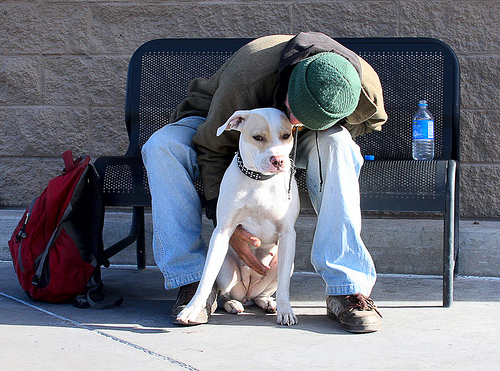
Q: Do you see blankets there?
A: No, there are no blankets.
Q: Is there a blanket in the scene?
A: No, there are no blankets.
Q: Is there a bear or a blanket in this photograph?
A: No, there are no blankets or bears.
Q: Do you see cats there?
A: No, there are no cats.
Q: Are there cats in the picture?
A: No, there are no cats.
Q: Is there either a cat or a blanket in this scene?
A: No, there are no cats or blankets.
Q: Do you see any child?
A: No, there are no children.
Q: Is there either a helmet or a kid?
A: No, there are no children or helmets.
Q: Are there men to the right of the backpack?
A: Yes, there is a man to the right of the backpack.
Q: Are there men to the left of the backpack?
A: No, the man is to the right of the backpack.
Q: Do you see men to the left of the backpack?
A: No, the man is to the right of the backpack.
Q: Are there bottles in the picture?
A: Yes, there is a bottle.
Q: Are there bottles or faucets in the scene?
A: Yes, there is a bottle.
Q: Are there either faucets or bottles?
A: Yes, there is a bottle.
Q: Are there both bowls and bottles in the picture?
A: No, there is a bottle but no bowls.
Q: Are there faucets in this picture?
A: No, there are no faucets.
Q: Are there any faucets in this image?
A: No, there are no faucets.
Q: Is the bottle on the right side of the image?
A: Yes, the bottle is on the right of the image.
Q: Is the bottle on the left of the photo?
A: No, the bottle is on the right of the image.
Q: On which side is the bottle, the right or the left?
A: The bottle is on the right of the image.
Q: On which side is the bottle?
A: The bottle is on the right of the image.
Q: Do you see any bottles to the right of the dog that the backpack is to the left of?
A: Yes, there is a bottle to the right of the dog.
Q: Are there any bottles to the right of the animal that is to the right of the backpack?
A: Yes, there is a bottle to the right of the dog.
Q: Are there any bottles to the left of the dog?
A: No, the bottle is to the right of the dog.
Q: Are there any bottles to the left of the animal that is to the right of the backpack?
A: No, the bottle is to the right of the dog.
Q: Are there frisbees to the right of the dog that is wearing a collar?
A: No, there is a bottle to the right of the dog.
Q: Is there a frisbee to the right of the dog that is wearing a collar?
A: No, there is a bottle to the right of the dog.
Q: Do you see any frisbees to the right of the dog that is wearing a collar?
A: No, there is a bottle to the right of the dog.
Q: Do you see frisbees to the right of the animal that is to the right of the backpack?
A: No, there is a bottle to the right of the dog.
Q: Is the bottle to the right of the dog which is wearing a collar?
A: Yes, the bottle is to the right of the dog.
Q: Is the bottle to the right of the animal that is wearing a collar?
A: Yes, the bottle is to the right of the dog.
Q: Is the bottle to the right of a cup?
A: No, the bottle is to the right of the dog.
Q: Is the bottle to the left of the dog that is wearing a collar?
A: No, the bottle is to the right of the dog.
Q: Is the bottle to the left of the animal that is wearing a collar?
A: No, the bottle is to the right of the dog.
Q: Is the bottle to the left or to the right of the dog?
A: The bottle is to the right of the dog.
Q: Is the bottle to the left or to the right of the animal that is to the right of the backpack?
A: The bottle is to the right of the dog.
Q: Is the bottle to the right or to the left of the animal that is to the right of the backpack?
A: The bottle is to the right of the dog.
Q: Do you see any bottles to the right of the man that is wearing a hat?
A: Yes, there is a bottle to the right of the man.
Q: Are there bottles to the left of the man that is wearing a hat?
A: No, the bottle is to the right of the man.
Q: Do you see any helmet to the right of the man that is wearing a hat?
A: No, there is a bottle to the right of the man.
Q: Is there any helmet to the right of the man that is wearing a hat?
A: No, there is a bottle to the right of the man.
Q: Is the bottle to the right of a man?
A: Yes, the bottle is to the right of a man.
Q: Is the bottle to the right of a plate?
A: No, the bottle is to the right of a man.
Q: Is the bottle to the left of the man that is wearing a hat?
A: No, the bottle is to the right of the man.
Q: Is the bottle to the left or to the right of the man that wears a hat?
A: The bottle is to the right of the man.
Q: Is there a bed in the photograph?
A: No, there are no beds.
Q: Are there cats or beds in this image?
A: No, there are no beds or cats.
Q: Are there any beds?
A: No, there are no beds.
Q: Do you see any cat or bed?
A: No, there are no beds or cats.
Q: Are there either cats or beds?
A: No, there are no beds or cats.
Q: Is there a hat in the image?
A: Yes, there is a hat.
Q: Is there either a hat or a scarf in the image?
A: Yes, there is a hat.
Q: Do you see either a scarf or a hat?
A: Yes, there is a hat.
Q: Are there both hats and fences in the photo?
A: No, there is a hat but no fences.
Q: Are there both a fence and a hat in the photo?
A: No, there is a hat but no fences.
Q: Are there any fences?
A: No, there are no fences.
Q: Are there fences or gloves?
A: No, there are no fences or gloves.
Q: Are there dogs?
A: Yes, there is a dog.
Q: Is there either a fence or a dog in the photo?
A: Yes, there is a dog.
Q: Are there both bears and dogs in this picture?
A: No, there is a dog but no bears.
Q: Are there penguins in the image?
A: No, there are no penguins.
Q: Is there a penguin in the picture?
A: No, there are no penguins.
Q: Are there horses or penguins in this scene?
A: No, there are no penguins or horses.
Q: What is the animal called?
A: The animal is a dog.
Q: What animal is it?
A: The animal is a dog.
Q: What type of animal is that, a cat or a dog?
A: That is a dog.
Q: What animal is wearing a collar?
A: The dog is wearing a collar.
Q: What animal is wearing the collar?
A: The dog is wearing a collar.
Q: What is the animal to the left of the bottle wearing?
A: The dog is wearing a collar.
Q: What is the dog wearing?
A: The dog is wearing a collar.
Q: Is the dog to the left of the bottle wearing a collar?
A: Yes, the dog is wearing a collar.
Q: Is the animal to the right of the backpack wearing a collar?
A: Yes, the dog is wearing a collar.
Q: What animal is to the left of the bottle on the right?
A: The animal is a dog.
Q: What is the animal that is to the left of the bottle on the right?
A: The animal is a dog.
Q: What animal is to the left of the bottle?
A: The animal is a dog.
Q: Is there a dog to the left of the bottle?
A: Yes, there is a dog to the left of the bottle.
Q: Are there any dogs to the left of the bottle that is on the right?
A: Yes, there is a dog to the left of the bottle.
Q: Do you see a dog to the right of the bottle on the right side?
A: No, the dog is to the left of the bottle.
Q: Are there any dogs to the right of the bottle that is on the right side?
A: No, the dog is to the left of the bottle.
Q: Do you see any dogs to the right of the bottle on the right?
A: No, the dog is to the left of the bottle.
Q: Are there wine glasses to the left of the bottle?
A: No, there is a dog to the left of the bottle.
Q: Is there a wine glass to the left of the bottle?
A: No, there is a dog to the left of the bottle.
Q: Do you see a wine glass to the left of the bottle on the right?
A: No, there is a dog to the left of the bottle.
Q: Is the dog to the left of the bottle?
A: Yes, the dog is to the left of the bottle.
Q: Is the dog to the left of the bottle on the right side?
A: Yes, the dog is to the left of the bottle.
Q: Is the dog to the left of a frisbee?
A: No, the dog is to the left of the bottle.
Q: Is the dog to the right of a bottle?
A: No, the dog is to the left of a bottle.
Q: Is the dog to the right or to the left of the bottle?
A: The dog is to the left of the bottle.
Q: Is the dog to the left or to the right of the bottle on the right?
A: The dog is to the left of the bottle.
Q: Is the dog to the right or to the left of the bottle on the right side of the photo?
A: The dog is to the left of the bottle.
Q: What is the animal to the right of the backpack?
A: The animal is a dog.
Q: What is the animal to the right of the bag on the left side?
A: The animal is a dog.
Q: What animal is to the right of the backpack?
A: The animal is a dog.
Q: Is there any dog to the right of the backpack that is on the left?
A: Yes, there is a dog to the right of the backpack.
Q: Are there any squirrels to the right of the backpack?
A: No, there is a dog to the right of the backpack.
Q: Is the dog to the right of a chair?
A: No, the dog is to the right of the backpack.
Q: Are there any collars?
A: Yes, there is a collar.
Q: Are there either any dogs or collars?
A: Yes, there is a collar.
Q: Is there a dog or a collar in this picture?
A: Yes, there is a collar.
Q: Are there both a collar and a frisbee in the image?
A: No, there is a collar but no frisbees.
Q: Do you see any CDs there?
A: No, there are no cds.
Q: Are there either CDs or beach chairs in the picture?
A: No, there are no CDs or beach chairs.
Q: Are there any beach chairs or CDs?
A: No, there are no CDs or beach chairs.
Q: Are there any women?
A: No, there are no women.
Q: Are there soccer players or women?
A: No, there are no women or soccer players.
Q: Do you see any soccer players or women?
A: No, there are no women or soccer players.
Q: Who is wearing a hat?
A: The man is wearing a hat.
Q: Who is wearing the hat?
A: The man is wearing a hat.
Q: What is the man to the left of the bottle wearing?
A: The man is wearing a hat.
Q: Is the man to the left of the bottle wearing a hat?
A: Yes, the man is wearing a hat.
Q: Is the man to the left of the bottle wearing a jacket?
A: No, the man is wearing a hat.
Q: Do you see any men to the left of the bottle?
A: Yes, there is a man to the left of the bottle.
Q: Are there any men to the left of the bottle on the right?
A: Yes, there is a man to the left of the bottle.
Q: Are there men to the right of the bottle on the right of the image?
A: No, the man is to the left of the bottle.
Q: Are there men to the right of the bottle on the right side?
A: No, the man is to the left of the bottle.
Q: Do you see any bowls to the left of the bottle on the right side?
A: No, there is a man to the left of the bottle.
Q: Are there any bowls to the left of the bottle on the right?
A: No, there is a man to the left of the bottle.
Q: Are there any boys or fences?
A: No, there are no fences or boys.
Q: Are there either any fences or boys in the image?
A: No, there are no fences or boys.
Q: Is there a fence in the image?
A: No, there are no fences.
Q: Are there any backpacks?
A: Yes, there is a backpack.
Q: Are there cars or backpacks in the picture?
A: Yes, there is a backpack.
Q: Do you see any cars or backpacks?
A: Yes, there is a backpack.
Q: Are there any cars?
A: No, there are no cars.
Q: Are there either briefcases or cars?
A: No, there are no cars or briefcases.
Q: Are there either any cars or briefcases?
A: No, there are no cars or briefcases.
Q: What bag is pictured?
A: The bag is a backpack.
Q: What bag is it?
A: The bag is a backpack.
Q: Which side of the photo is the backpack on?
A: The backpack is on the left of the image.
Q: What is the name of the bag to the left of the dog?
A: The bag is a backpack.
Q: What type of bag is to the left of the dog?
A: The bag is a backpack.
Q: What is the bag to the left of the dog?
A: The bag is a backpack.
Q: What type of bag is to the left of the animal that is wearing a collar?
A: The bag is a backpack.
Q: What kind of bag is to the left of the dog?
A: The bag is a backpack.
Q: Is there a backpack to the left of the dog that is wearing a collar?
A: Yes, there is a backpack to the left of the dog.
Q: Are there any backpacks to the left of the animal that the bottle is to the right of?
A: Yes, there is a backpack to the left of the dog.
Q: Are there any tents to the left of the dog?
A: No, there is a backpack to the left of the dog.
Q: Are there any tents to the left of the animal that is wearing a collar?
A: No, there is a backpack to the left of the dog.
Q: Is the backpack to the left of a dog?
A: Yes, the backpack is to the left of a dog.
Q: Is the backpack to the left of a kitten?
A: No, the backpack is to the left of a dog.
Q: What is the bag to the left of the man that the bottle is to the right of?
A: The bag is a backpack.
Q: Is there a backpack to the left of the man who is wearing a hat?
A: Yes, there is a backpack to the left of the man.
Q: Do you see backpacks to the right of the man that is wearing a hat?
A: No, the backpack is to the left of the man.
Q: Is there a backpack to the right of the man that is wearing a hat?
A: No, the backpack is to the left of the man.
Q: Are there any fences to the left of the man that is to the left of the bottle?
A: No, there is a backpack to the left of the man.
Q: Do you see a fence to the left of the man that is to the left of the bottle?
A: No, there is a backpack to the left of the man.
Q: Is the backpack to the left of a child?
A: No, the backpack is to the left of a man.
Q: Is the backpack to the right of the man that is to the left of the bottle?
A: No, the backpack is to the left of the man.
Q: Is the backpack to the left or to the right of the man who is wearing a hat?
A: The backpack is to the left of the man.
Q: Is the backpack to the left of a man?
A: Yes, the backpack is to the left of a man.